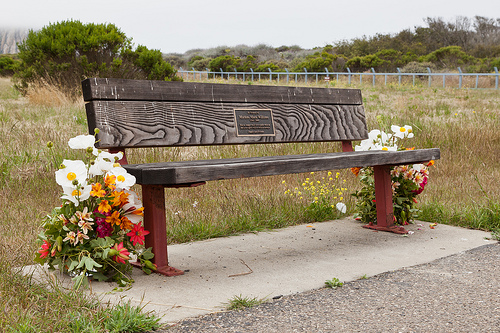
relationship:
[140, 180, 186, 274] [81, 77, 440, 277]
leg of bench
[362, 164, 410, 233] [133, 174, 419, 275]
leg of metal legs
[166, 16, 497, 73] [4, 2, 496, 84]
treeline in background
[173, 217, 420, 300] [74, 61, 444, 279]
cement platform for bench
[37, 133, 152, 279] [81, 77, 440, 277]
flower near bench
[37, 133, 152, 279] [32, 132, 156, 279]
flower has bouquet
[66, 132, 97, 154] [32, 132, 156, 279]
flower has bouquet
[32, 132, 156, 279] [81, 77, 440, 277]
bouquet next to bench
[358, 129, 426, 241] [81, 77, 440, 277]
bouquet next to bench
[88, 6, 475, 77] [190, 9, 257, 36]
cover in sky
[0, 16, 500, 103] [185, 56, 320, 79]
trees have line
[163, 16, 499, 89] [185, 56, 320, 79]
trees have line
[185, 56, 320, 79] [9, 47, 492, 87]
line on horizon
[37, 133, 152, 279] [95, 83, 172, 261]
flower on side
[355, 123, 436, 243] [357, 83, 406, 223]
flowers on side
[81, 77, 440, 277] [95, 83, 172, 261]
bench has side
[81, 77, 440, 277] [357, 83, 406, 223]
bench has side